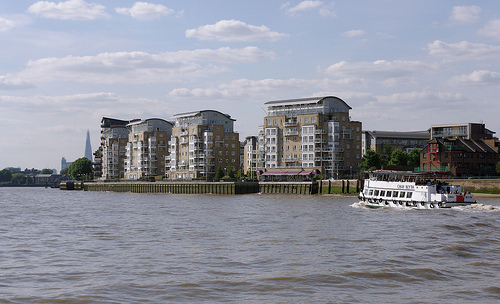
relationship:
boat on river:
[357, 167, 476, 210] [369, 146, 454, 238]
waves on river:
[454, 202, 499, 214] [0, 186, 499, 301]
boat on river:
[357, 167, 476, 210] [0, 186, 499, 301]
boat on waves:
[357, 167, 476, 210] [454, 202, 499, 214]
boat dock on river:
[58, 175, 365, 195] [0, 186, 499, 301]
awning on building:
[262, 167, 316, 175] [243, 95, 362, 180]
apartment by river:
[247, 97, 362, 187] [0, 186, 499, 301]